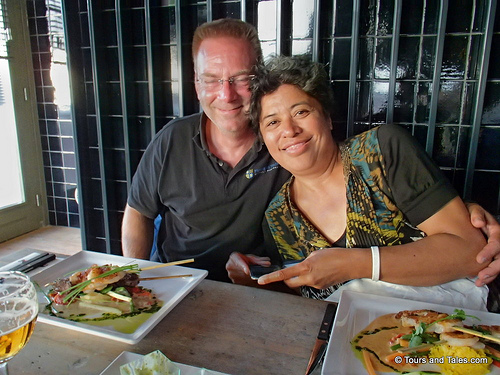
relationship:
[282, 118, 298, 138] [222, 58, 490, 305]
nose on someone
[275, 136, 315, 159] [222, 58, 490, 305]
mouth on someone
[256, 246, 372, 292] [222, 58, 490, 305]
hand on someone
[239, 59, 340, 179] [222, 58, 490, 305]
head on someone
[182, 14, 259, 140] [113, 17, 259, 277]
head on man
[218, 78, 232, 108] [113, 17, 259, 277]
nose on man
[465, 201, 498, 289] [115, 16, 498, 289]
hand on man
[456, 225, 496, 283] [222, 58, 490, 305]
elbow on someone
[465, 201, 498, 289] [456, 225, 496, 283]
hand holding elbow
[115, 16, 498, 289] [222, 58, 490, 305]
man holding someone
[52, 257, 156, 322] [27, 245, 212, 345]
vegetables on plate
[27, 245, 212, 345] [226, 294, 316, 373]
plate on table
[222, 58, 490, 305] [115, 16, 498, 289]
someone leaning on man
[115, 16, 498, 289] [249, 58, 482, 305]
man holding someone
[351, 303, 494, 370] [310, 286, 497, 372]
food on plate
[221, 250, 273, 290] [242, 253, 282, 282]
hand holding cell phone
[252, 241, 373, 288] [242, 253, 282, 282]
hand holding cell phone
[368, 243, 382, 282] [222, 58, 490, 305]
band on someone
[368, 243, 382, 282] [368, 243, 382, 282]
band around band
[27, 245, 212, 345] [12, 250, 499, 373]
plate sitting on table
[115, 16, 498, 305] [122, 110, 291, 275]
man wearing shirt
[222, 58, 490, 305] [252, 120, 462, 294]
someone wearing top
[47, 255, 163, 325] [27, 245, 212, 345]
food sitting on plate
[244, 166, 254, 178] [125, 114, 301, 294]
logo on shirt